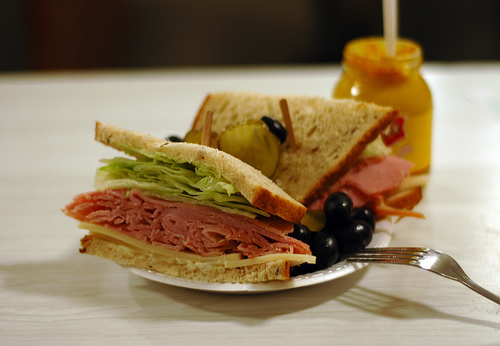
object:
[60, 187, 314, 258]
meat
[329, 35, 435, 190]
mustard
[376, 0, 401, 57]
utensil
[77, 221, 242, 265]
cheese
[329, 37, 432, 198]
bottle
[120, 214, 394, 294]
dish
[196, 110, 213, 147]
toothpick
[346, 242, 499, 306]
fork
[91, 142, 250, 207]
lettuce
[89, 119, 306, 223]
bread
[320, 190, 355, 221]
olives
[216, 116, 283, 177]
pickle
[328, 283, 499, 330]
shadow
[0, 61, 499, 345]
table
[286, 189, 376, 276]
olive pile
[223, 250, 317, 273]
cheese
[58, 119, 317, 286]
sandwich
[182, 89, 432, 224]
sandwich